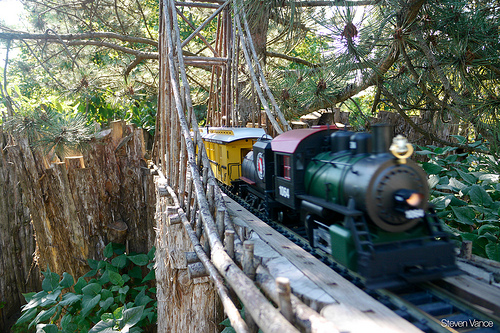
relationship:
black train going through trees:
[190, 128, 462, 289] [2, 2, 498, 117]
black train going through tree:
[190, 128, 462, 289] [265, 0, 496, 258]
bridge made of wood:
[153, 0, 500, 333] [258, 236, 325, 301]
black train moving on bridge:
[190, 128, 462, 289] [153, 0, 500, 333]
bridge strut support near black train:
[141, 5, 276, 332] [190, 128, 462, 289]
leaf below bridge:
[128, 247, 155, 268] [153, 0, 500, 333]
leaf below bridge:
[55, 267, 75, 289] [153, 0, 500, 333]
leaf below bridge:
[471, 181, 492, 205] [153, 0, 500, 333]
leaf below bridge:
[115, 106, 130, 120] [153, 0, 500, 333]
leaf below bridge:
[57, 290, 84, 310] [153, 0, 500, 333]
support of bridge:
[154, 212, 219, 332] [141, 4, 429, 331]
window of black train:
[275, 150, 292, 179] [190, 128, 462, 289]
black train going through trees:
[190, 128, 462, 289] [23, 0, 498, 145]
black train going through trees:
[190, 128, 462, 289] [273, 9, 498, 133]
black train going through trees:
[190, 128, 462, 289] [44, 12, 151, 102]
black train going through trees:
[190, 128, 462, 289] [44, 73, 150, 123]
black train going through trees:
[190, 128, 462, 289] [190, 64, 422, 121]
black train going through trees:
[198, 119, 464, 291] [38, 4, 163, 93]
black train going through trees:
[190, 128, 462, 289] [361, 32, 483, 130]